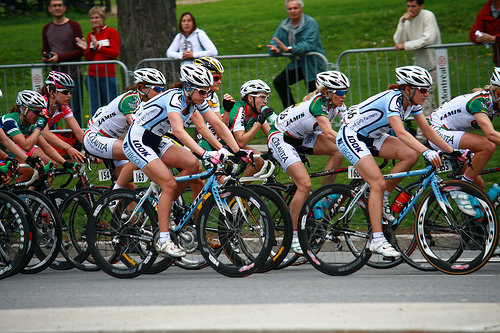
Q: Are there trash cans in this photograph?
A: No, there are no trash cans.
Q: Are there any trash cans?
A: No, there are no trash cans.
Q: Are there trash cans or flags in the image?
A: No, there are no trash cans or flags.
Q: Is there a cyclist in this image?
A: Yes, there is a cyclist.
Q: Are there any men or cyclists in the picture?
A: Yes, there is a cyclist.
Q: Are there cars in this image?
A: No, there are no cars.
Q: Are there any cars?
A: No, there are no cars.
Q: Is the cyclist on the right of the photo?
A: Yes, the cyclist is on the right of the image.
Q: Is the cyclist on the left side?
A: No, the cyclist is on the right of the image.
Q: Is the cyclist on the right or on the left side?
A: The cyclist is on the right of the image.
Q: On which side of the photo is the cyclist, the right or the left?
A: The cyclist is on the right of the image.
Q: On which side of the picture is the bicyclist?
A: The bicyclist is on the right of the image.